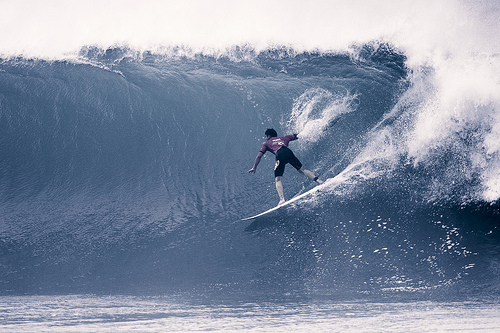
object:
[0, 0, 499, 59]
skies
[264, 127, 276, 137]
hair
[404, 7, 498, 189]
whitewater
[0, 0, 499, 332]
wave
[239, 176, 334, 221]
surfboard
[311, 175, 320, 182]
strap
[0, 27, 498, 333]
water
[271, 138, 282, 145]
writing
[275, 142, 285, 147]
design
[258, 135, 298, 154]
clothing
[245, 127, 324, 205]
man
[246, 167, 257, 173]
hand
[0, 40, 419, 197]
wave wall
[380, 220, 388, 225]
foam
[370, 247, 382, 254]
foam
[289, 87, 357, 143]
white water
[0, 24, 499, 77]
crest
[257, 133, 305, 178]
suit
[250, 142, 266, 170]
arm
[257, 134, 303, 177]
outfit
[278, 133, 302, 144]
arms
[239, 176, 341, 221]
board